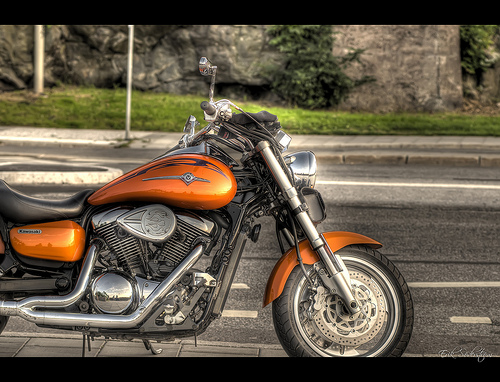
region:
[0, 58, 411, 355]
The motorcycle body is orange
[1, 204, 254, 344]
Engine is V twin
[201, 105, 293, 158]
Gloves are above headlights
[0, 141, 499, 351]
Street is behind motorcycle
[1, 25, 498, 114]
Background is rock wall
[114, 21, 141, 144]
Metal pole is in background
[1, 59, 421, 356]
Motorcycle is on kickstand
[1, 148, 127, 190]
Concrete island is in street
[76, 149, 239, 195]
Black tribal marks on body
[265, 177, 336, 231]
Bag is strapped to bike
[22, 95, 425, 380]
the bike is parked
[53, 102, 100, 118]
the grass is green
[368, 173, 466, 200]
the line is white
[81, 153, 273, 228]
the gas tank is orange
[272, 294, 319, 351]
the wheel is black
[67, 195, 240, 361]
the engines are silver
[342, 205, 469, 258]
the street is gray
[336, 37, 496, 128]
the rock is brown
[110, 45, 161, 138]
the pole is gray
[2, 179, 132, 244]
the seat is made of leather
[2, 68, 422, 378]
A motorcycle is on the sidewalk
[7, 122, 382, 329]
Motorcycle has orange body parts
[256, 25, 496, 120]
A tree is in the background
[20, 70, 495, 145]
Grass is in the background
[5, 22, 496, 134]
Heavy rocks is in the background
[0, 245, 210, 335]
Motorcycle has sliver pipes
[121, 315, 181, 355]
Motorcycle has kickstand down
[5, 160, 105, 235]
Motorcycle seat is made of leather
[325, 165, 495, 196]
White line is in the street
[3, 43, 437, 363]
The motorcycle is at a side view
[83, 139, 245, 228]
the tank is orange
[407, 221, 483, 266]
the street is gray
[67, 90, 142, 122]
the grass is green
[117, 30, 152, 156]
the pole is white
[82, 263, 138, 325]
the metal is shiny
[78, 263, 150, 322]
the metal is silver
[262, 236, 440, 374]
the tire is round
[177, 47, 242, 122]
the mirror is metal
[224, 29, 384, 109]
the rock is gray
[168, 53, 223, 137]
Side view mirrors on the motorcycle.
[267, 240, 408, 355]
Front wheel of the motorcycle.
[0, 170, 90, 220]
Black seat of the motorcycle.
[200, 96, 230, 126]
Handlebar in the front of the motorcycle.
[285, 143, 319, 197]
Front headlight on the motorcycle.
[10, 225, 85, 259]
Orange area under the black seat.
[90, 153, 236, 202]
Large orange area in front of the black seat.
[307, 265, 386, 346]
Circle chrome structure in the inside of the front wheel.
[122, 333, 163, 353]
The kickstand holding up the motorcycle.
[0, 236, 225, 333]
Chrome pipes on the side of the motorcycle.